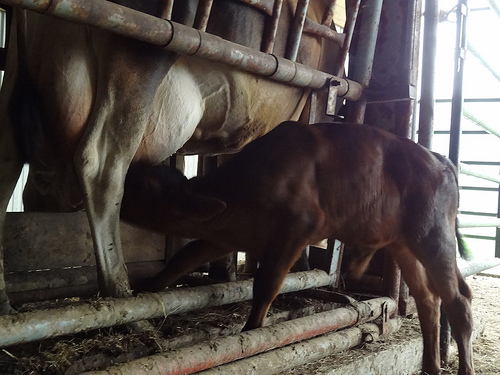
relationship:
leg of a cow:
[410, 232, 470, 374] [165, 154, 490, 290]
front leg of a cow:
[244, 206, 305, 346] [165, 154, 490, 290]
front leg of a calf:
[244, 206, 305, 346] [169, 104, 496, 330]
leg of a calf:
[410, 232, 470, 374] [169, 104, 496, 330]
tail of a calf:
[439, 201, 489, 274] [169, 104, 496, 330]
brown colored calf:
[299, 134, 387, 227] [169, 104, 496, 330]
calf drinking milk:
[169, 104, 496, 330] [110, 145, 178, 251]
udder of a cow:
[141, 68, 235, 166] [165, 154, 490, 290]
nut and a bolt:
[325, 63, 355, 107] [318, 66, 339, 92]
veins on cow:
[146, 75, 264, 140] [165, 154, 490, 290]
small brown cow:
[169, 104, 496, 330] [165, 154, 490, 290]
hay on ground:
[99, 327, 182, 363] [93, 299, 268, 374]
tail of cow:
[439, 201, 489, 274] [165, 154, 490, 290]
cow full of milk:
[165, 154, 490, 290] [110, 145, 178, 251]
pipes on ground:
[154, 282, 379, 371] [93, 299, 268, 374]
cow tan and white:
[49, 39, 272, 130] [26, 36, 264, 289]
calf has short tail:
[169, 104, 496, 330] [439, 201, 489, 274]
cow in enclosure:
[165, 154, 490, 290] [11, 2, 393, 160]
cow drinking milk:
[165, 154, 490, 290] [110, 145, 178, 251]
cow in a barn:
[165, 154, 490, 290] [10, 15, 490, 363]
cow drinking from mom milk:
[165, 154, 490, 290] [110, 145, 178, 251]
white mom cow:
[26, 36, 264, 289] [165, 154, 490, 290]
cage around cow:
[167, 15, 424, 95] [165, 154, 490, 290]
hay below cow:
[99, 327, 182, 363] [165, 154, 490, 290]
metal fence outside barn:
[155, 20, 498, 149] [10, 15, 490, 363]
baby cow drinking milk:
[169, 104, 496, 330] [110, 145, 178, 251]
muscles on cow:
[236, 124, 472, 256] [165, 154, 490, 290]